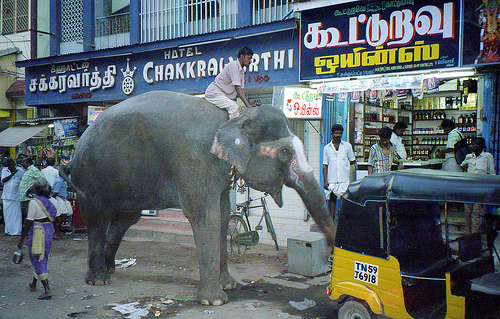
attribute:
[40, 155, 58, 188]
person — standing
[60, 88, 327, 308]
elephant — large, grey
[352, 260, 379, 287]
sign — white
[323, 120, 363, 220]
person — standing up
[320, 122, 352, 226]
person — standing